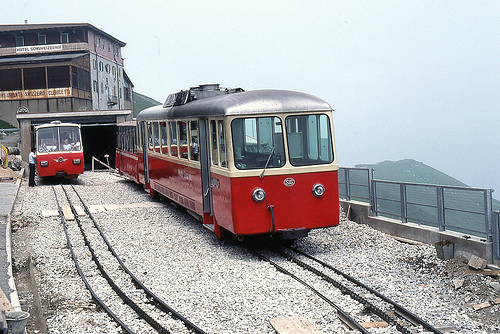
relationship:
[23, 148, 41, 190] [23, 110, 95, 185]
man next to train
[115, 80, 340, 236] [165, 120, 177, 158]
train has window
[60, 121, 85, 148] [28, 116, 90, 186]
window on train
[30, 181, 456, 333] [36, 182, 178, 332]
gravel on track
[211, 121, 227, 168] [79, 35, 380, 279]
window on train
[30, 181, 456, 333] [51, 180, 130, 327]
gravel on track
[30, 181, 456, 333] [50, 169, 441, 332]
gravel on track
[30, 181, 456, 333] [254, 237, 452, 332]
gravel on track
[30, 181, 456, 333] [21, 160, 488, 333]
gravel on track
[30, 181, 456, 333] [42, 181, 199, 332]
gravel on track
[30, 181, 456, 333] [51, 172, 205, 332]
gravel on track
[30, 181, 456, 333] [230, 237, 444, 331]
gravel on track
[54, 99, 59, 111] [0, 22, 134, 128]
rust stains on building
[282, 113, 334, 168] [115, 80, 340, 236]
window on train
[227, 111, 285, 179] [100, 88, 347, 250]
window on train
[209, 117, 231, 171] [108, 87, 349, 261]
window on train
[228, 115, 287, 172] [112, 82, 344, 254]
window on train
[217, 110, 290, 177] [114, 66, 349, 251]
window on train